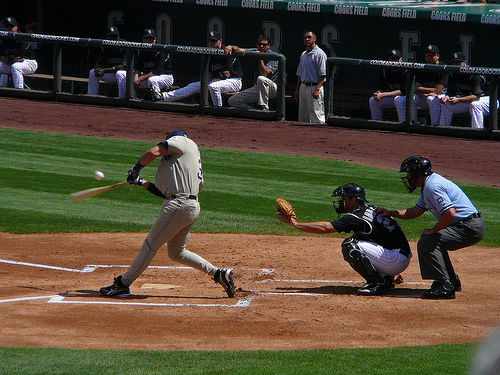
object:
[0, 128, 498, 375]
grass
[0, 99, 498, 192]
dirt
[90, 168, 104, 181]
ball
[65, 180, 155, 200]
baseball bat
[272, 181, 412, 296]
catcher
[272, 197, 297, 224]
mitt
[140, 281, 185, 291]
home plate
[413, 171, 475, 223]
shirt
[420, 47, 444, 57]
helmets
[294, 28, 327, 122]
man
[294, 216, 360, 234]
arm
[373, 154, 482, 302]
umpire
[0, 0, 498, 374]
air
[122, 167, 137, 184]
glove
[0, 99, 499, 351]
clay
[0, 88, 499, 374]
ground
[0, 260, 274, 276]
lines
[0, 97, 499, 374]
field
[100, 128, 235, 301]
batter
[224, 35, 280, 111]
players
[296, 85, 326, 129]
pants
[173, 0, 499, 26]
banner